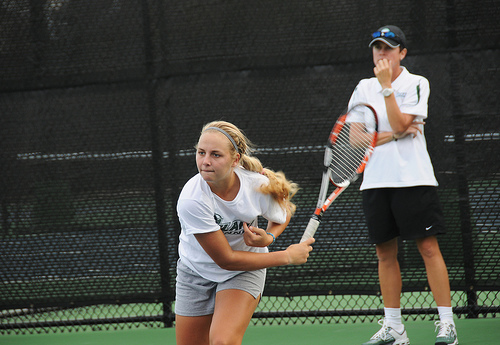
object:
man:
[343, 24, 458, 345]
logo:
[213, 213, 257, 234]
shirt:
[178, 166, 288, 284]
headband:
[204, 127, 239, 153]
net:
[6, 3, 498, 327]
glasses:
[368, 31, 400, 42]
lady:
[174, 120, 316, 344]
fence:
[2, 2, 500, 334]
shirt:
[344, 66, 440, 191]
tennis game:
[1, 100, 480, 345]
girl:
[173, 121, 315, 344]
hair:
[198, 121, 301, 216]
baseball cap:
[368, 25, 406, 48]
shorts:
[174, 256, 267, 317]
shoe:
[357, 326, 411, 344]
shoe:
[431, 321, 458, 345]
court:
[0, 287, 500, 343]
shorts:
[361, 181, 446, 244]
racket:
[298, 103, 379, 246]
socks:
[435, 306, 453, 325]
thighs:
[206, 288, 260, 345]